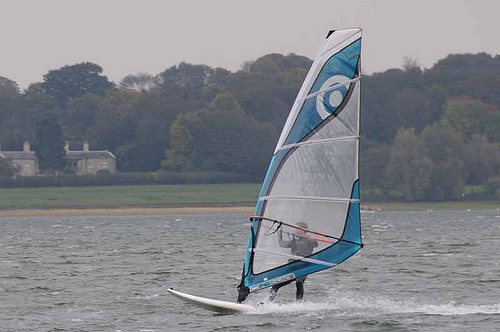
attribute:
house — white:
[0, 140, 119, 186]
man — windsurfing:
[277, 222, 326, 303]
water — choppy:
[2, 214, 500, 332]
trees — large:
[2, 54, 498, 200]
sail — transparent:
[245, 28, 365, 290]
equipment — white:
[166, 27, 365, 310]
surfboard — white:
[163, 284, 385, 319]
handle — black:
[248, 212, 365, 245]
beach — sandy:
[0, 203, 269, 218]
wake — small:
[241, 292, 495, 325]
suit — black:
[267, 236, 320, 305]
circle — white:
[313, 73, 358, 119]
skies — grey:
[2, 2, 499, 94]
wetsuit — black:
[273, 229, 317, 291]